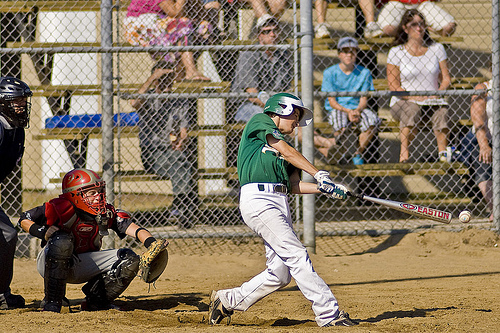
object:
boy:
[173, 81, 353, 326]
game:
[26, 37, 458, 317]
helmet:
[59, 166, 112, 218]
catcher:
[9, 170, 173, 309]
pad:
[65, 252, 156, 318]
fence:
[79, 27, 210, 222]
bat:
[286, 164, 472, 255]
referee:
[0, 73, 35, 313]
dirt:
[388, 266, 446, 312]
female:
[383, 9, 453, 167]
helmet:
[259, 91, 318, 127]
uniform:
[232, 78, 344, 212]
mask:
[76, 179, 94, 211]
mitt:
[136, 216, 173, 280]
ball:
[455, 209, 473, 225]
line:
[168, 273, 212, 302]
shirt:
[316, 59, 375, 117]